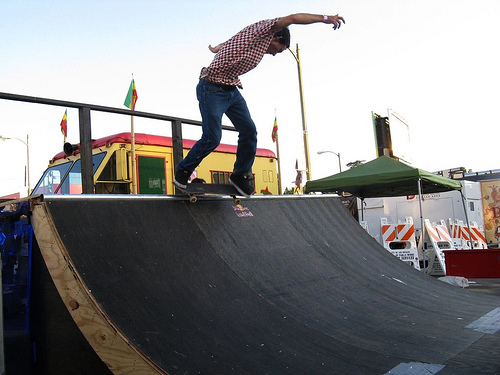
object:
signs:
[379, 216, 488, 276]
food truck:
[30, 132, 279, 196]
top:
[52, 132, 275, 161]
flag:
[123, 79, 137, 109]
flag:
[60, 108, 67, 138]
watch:
[323, 15, 328, 23]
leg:
[225, 105, 257, 174]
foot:
[229, 173, 251, 197]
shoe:
[228, 173, 251, 197]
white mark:
[393, 277, 408, 286]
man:
[173, 12, 346, 195]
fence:
[444, 249, 500, 278]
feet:
[174, 169, 193, 190]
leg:
[176, 88, 222, 172]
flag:
[272, 117, 278, 143]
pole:
[272, 109, 282, 195]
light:
[287, 43, 299, 60]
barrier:
[378, 216, 420, 272]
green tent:
[305, 155, 463, 274]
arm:
[272, 13, 324, 32]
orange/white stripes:
[382, 224, 414, 241]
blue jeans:
[177, 79, 258, 173]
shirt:
[199, 17, 281, 90]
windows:
[30, 152, 106, 196]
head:
[266, 28, 291, 56]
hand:
[325, 14, 344, 31]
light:
[317, 151, 338, 157]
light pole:
[288, 43, 313, 180]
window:
[136, 154, 167, 195]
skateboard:
[172, 182, 255, 205]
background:
[0, 44, 498, 194]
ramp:
[0, 193, 500, 375]